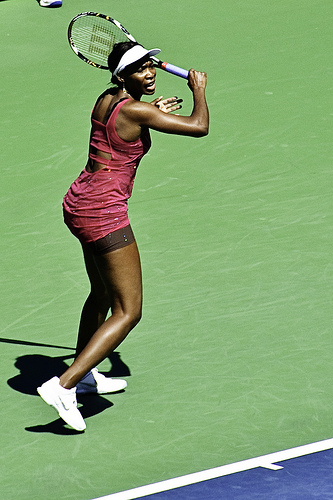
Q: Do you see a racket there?
A: Yes, there is a racket.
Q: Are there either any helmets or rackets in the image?
A: Yes, there is a racket.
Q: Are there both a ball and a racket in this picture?
A: No, there is a racket but no balls.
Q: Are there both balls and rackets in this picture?
A: No, there is a racket but no balls.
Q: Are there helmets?
A: No, there are no helmets.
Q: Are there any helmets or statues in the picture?
A: No, there are no helmets or statues.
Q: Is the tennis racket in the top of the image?
A: Yes, the tennis racket is in the top of the image.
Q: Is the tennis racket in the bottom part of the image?
A: No, the tennis racket is in the top of the image.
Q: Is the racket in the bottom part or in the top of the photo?
A: The racket is in the top of the image.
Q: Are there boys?
A: No, there are no boys.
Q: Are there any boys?
A: No, there are no boys.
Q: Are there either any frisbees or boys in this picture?
A: No, there are no boys or frisbees.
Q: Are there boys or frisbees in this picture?
A: No, there are no boys or frisbees.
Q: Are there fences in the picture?
A: No, there are no fences.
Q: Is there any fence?
A: No, there are no fences.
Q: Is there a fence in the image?
A: No, there are no fences.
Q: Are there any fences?
A: No, there are no fences.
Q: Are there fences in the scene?
A: No, there are no fences.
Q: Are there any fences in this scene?
A: No, there are no fences.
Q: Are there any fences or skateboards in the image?
A: No, there are no fences or skateboards.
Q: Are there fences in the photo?
A: No, there are no fences.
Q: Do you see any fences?
A: No, there are no fences.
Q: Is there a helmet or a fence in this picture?
A: No, there are no fences or helmets.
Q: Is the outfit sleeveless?
A: Yes, the outfit is sleeveless.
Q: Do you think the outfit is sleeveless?
A: Yes, the outfit is sleeveless.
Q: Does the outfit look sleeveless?
A: Yes, the outfit is sleeveless.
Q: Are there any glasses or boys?
A: No, there are no boys or glasses.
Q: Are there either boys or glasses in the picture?
A: No, there are no boys or glasses.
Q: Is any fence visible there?
A: No, there are no fences.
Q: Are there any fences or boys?
A: No, there are no fences or boys.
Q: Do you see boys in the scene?
A: No, there are no boys.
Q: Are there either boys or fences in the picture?
A: No, there are no boys or fences.